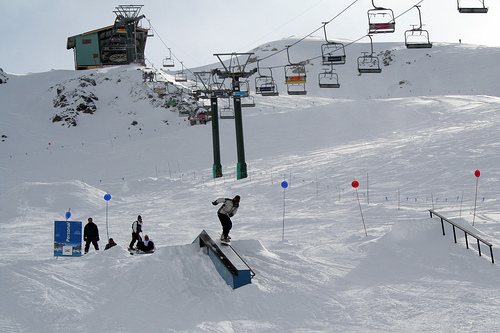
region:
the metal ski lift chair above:
[253, 73, 274, 94]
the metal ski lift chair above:
[257, 81, 279, 100]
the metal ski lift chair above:
[284, 58, 306, 83]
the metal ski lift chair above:
[285, 78, 305, 96]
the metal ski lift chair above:
[321, 41, 347, 66]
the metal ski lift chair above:
[317, 70, 339, 90]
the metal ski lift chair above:
[357, 52, 379, 74]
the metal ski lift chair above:
[365, 7, 395, 34]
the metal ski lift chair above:
[405, 27, 430, 50]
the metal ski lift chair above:
[162, 57, 174, 67]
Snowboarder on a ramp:
[195, 193, 254, 290]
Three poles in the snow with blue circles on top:
[53, 168, 293, 234]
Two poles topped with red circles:
[348, 168, 483, 250]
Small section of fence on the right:
[425, 207, 495, 269]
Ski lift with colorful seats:
[65, 1, 499, 181]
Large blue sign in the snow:
[53, 219, 84, 259]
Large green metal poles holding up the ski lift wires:
[194, 67, 259, 179]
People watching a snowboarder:
[82, 192, 154, 257]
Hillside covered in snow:
[3, 32, 499, 332]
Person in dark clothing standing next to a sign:
[52, 216, 101, 256]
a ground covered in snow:
[319, 239, 451, 331]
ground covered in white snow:
[335, 232, 428, 324]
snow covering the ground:
[312, 252, 412, 327]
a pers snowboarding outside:
[130, 151, 292, 314]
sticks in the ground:
[262, 149, 404, 296]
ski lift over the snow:
[190, 14, 395, 120]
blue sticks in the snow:
[262, 159, 307, 254]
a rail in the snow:
[389, 174, 496, 307]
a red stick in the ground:
[322, 156, 406, 295]